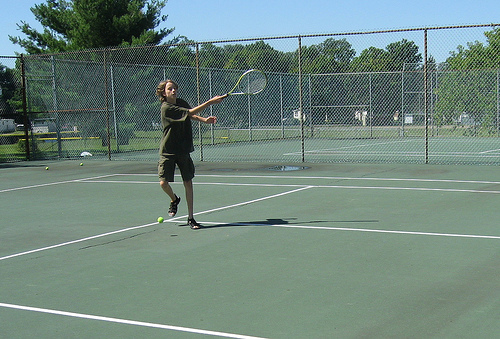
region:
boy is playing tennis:
[134, 47, 298, 219]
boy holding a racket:
[150, 41, 285, 268]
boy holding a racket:
[192, 39, 293, 114]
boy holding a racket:
[147, 68, 292, 150]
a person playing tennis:
[146, 64, 276, 234]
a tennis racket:
[209, 62, 271, 107]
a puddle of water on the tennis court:
[207, 159, 311, 179]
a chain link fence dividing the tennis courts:
[16, 25, 499, 170]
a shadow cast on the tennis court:
[198, 205, 382, 240]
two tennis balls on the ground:
[31, 160, 91, 172]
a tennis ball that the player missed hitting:
[153, 213, 170, 228]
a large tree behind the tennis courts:
[18, 0, 173, 151]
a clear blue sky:
[163, 1, 498, 45]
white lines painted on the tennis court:
[75, 170, 499, 198]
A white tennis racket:
[216, 64, 270, 101]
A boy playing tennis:
[148, 69, 231, 233]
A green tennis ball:
[154, 215, 166, 225]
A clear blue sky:
[183, 1, 333, 28]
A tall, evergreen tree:
[14, 2, 161, 149]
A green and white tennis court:
[2, 168, 498, 336]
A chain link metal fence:
[30, 24, 495, 163]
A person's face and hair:
[154, 78, 181, 105]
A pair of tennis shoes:
[163, 198, 201, 233]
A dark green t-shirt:
[157, 99, 198, 161]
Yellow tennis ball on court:
[155, 215, 165, 225]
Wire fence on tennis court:
[297, 32, 434, 168]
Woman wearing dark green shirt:
[157, 78, 199, 158]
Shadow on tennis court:
[200, 213, 381, 230]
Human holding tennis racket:
[157, 65, 267, 125]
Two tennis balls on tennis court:
[40, 158, 87, 170]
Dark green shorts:
[155, 150, 197, 181]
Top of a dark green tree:
[30, 1, 170, 38]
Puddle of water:
[271, 161, 306, 168]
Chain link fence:
[422, 25, 489, 166]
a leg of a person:
[180, 157, 197, 217]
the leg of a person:
[159, 157, 177, 200]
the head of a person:
[154, 72, 184, 100]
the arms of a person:
[180, 95, 212, 123]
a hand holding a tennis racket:
[214, 66, 269, 104]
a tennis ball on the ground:
[153, 212, 168, 227]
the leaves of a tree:
[72, 11, 117, 41]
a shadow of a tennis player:
[204, 210, 379, 232]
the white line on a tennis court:
[314, 180, 414, 192]